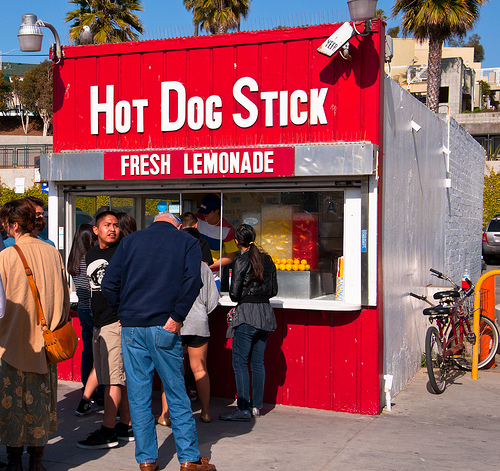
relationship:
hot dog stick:
[89, 81, 151, 140] [231, 76, 330, 129]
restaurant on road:
[51, 48, 374, 179] [365, 420, 478, 470]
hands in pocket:
[160, 317, 183, 334] [156, 333, 178, 352]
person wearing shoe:
[121, 209, 200, 470] [181, 459, 216, 471]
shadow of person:
[200, 421, 248, 446] [121, 209, 200, 470]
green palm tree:
[412, 0, 471, 25] [425, 0, 444, 108]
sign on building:
[71, 60, 333, 143] [51, 48, 374, 179]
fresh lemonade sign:
[117, 152, 174, 179] [104, 149, 294, 186]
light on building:
[19, 11, 64, 71] [51, 48, 374, 179]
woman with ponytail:
[228, 223, 276, 420] [247, 240, 262, 283]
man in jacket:
[121, 209, 200, 470] [123, 230, 191, 319]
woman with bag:
[3, 204, 76, 470] [42, 322, 77, 360]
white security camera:
[338, 28, 348, 43] [316, 24, 353, 64]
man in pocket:
[121, 209, 200, 470] [156, 333, 178, 352]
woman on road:
[3, 204, 76, 470] [0, 370, 499, 471]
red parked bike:
[335, 328, 354, 362] [410, 269, 500, 395]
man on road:
[91, 211, 121, 244] [0, 370, 499, 471]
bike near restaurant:
[416, 284, 470, 394] [46, 21, 484, 415]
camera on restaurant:
[316, 24, 353, 64] [46, 21, 484, 415]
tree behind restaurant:
[425, 0, 444, 108] [46, 21, 484, 415]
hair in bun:
[3, 204, 39, 239] [26, 219, 48, 233]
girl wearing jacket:
[228, 223, 276, 420] [231, 255, 277, 308]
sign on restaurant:
[71, 60, 333, 143] [46, 21, 484, 415]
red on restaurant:
[335, 328, 354, 362] [46, 21, 484, 415]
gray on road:
[297, 419, 334, 441] [0, 370, 499, 471]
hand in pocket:
[160, 317, 183, 334] [156, 333, 178, 352]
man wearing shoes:
[121, 209, 200, 470] [138, 462, 220, 470]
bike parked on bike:
[416, 284, 470, 394] [410, 269, 500, 395]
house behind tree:
[392, 33, 475, 88] [425, 0, 444, 108]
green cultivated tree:
[412, 0, 471, 25] [425, 0, 444, 108]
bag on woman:
[42, 322, 77, 360] [3, 204, 76, 470]